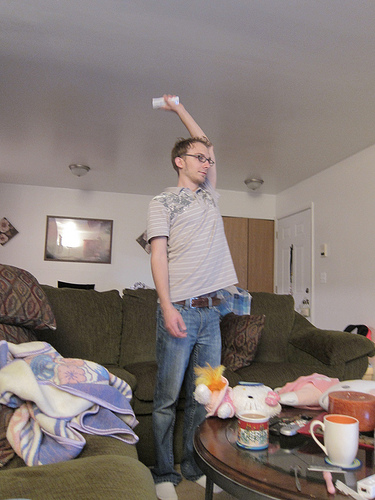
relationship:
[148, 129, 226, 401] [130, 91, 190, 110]
man with gamecontroller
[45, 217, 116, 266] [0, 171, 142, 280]
picture on wall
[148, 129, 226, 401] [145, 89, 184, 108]
man playing wii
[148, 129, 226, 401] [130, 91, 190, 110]
man holding controller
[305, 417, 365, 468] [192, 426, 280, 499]
cups on table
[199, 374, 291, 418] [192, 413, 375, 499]
kittydolls on table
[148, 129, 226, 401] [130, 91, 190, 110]
man holding gamecontroller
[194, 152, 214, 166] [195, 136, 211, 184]
glasses on mansface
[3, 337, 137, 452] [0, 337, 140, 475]
blanket on blanket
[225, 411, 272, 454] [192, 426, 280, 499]
coffee sitting on table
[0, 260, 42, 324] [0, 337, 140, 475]
pillow on blanket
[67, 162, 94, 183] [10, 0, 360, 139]
light on ceiling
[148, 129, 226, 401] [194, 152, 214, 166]
man wearing eyeglasses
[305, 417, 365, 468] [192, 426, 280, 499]
mug on table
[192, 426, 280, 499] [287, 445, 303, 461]
table has glasstop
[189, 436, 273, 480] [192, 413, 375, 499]
wood on table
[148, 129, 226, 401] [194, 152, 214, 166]
man wearing glasses